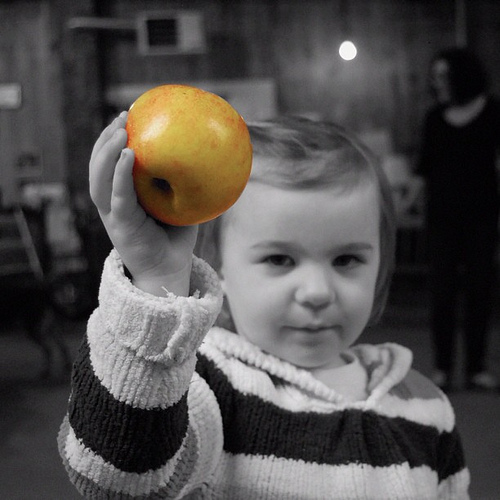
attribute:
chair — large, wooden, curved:
[0, 196, 73, 384]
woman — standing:
[412, 49, 497, 394]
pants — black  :
[428, 254, 488, 369]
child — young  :
[44, 49, 486, 492]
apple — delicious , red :
[119, 82, 255, 228]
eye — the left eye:
[330, 252, 365, 269]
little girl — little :
[53, 91, 473, 499]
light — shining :
[334, 36, 362, 65]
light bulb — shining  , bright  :
[335, 37, 360, 64]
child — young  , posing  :
[50, 71, 465, 494]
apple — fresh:
[129, 92, 231, 225]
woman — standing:
[392, 44, 497, 404]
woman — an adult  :
[401, 58, 497, 397]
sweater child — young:
[54, 76, 479, 479]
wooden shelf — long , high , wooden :
[65, 15, 231, 34]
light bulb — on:
[340, 40, 356, 61]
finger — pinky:
[111, 150, 135, 215]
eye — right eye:
[252, 253, 297, 267]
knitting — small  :
[260, 400, 275, 417]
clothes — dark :
[412, 103, 496, 372]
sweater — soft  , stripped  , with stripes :
[61, 251, 471, 498]